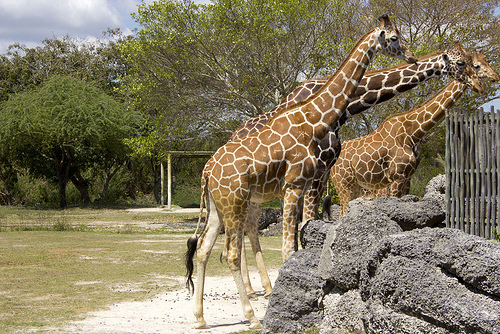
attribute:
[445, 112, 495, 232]
fence — wooden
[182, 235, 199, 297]
hair — black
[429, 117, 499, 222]
fencing — wood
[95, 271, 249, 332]
ground — sandy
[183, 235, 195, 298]
hair — black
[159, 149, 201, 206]
structure — wooden, outdoor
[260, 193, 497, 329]
fence — big, grey, rock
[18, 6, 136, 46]
sky — cloudy, blue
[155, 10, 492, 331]
giraffes — captive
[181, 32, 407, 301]
giraffe — black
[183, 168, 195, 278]
tail — long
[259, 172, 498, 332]
rocks — grey, porous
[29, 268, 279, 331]
dirt — white, sandy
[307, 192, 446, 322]
rocks — barrier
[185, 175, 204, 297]
tail — black, bushy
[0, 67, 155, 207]
tree — green, medium-sized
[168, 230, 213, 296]
hair — black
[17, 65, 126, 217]
tree — large, green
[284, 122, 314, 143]
spots — brown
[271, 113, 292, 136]
spots — brown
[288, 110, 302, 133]
spots — brown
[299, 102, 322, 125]
spots — brown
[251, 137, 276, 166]
spots — brown